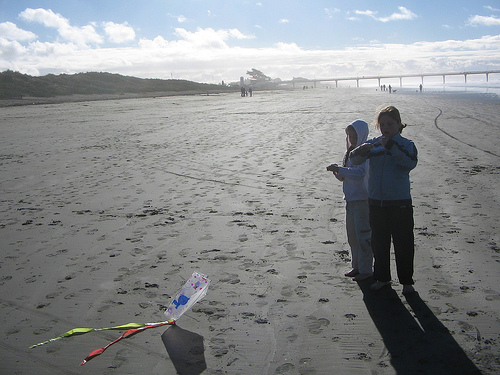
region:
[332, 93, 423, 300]
two children on the beach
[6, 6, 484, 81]
the cloudy sky above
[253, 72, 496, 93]
the long bridge above the water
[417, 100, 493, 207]
a bike trail on the beach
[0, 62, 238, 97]
the hill next to the beach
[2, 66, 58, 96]
the green leaves and grass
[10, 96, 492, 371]
the beach with many footprints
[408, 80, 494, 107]
the ocean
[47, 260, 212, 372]
the kite to be flown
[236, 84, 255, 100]
the family on the beach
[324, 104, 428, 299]
two little girls, somehow in shadow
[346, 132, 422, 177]
girl holds kite string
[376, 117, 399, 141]
girl's face conveys concentration as she watches kite string wind & unwind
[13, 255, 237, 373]
kite on ground amid muddy footprints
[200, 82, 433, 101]
a few people on the sand in the very far distance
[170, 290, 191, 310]
kite has print of bright blue animal on it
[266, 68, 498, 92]
long+narrow white bridge in far distance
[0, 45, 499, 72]
very long cumulonimbus or stratus cloud across distant horizon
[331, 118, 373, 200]
little girl in pale colored hoodie with the hood up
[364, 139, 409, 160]
dark+light blue horizontal stripes on little girl's little puffy jacket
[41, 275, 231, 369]
a kite on the beach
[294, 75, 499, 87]
a bridge over the water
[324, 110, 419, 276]
two kids on the beach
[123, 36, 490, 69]
the cloudy sky above it all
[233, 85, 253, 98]
a family on the beach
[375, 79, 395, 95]
friends on the beach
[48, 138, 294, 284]
footprints on the beach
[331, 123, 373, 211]
the hoodie on the child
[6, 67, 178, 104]
a hill with the plants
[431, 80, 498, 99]
the ocean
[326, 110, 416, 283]
Two barefoot girls standing on a beach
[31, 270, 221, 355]
a kite lying in the sand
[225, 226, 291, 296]
foot prints in the sand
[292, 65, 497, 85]
a bridge in the background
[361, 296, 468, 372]
the shadow of the girls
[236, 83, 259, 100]
people in the distance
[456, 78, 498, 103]
the edge of the water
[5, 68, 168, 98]
a patch of vegetation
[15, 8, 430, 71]
clouds on the horizon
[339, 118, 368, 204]
girl is wearing a hooded jacket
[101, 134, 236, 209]
The brown sand with footprints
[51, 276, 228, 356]
A kite on the ground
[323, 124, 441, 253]
Two people standing on the beach.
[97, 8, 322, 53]
White clouds in the sky.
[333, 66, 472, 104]
A bridge in the background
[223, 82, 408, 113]
People standing around.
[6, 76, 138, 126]
A hill in the background.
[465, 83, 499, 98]
Water in the background.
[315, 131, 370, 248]
A kid with a hood.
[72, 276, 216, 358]
A colorful kite.